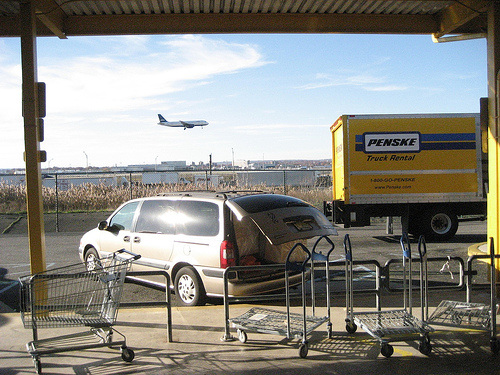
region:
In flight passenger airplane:
[156, 112, 210, 128]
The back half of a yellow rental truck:
[331, 113, 485, 236]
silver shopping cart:
[21, 253, 138, 369]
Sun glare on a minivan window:
[140, 200, 220, 236]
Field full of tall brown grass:
[46, 178, 126, 205]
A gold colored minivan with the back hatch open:
[90, 194, 327, 294]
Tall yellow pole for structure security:
[21, 27, 48, 312]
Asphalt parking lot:
[47, 237, 77, 268]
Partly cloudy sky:
[128, 38, 432, 99]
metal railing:
[138, 270, 179, 344]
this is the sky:
[232, 52, 297, 119]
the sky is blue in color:
[295, 40, 342, 67]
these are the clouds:
[158, 52, 207, 83]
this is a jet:
[151, 111, 210, 133]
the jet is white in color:
[193, 117, 208, 127]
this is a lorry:
[338, 106, 485, 235]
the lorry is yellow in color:
[421, 151, 474, 163]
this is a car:
[116, 190, 261, 251]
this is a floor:
[148, 338, 214, 369]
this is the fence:
[56, 175, 103, 205]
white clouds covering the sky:
[54, 75, 131, 127]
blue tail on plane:
[155, 112, 167, 132]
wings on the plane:
[173, 119, 205, 138]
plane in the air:
[133, 105, 246, 140]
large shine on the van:
[145, 193, 207, 234]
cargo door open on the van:
[215, 171, 353, 255]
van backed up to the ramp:
[78, 182, 328, 292]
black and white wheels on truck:
[415, 195, 460, 248]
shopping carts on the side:
[176, 233, 403, 348]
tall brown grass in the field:
[65, 179, 249, 196]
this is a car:
[135, 180, 226, 299]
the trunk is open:
[237, 198, 298, 261]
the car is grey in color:
[176, 239, 218, 267]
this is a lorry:
[335, 117, 452, 204]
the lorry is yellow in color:
[342, 120, 451, 190]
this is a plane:
[149, 109, 214, 135]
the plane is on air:
[155, 107, 215, 132]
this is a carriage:
[20, 248, 139, 362]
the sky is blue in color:
[319, 37, 406, 69]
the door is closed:
[110, 227, 131, 240]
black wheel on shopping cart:
[106, 335, 160, 365]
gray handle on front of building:
[133, 270, 203, 344]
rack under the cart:
[26, 331, 129, 351]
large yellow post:
[10, 85, 62, 285]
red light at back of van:
[209, 240, 246, 267]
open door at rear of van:
[188, 180, 352, 267]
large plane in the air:
[148, 113, 207, 133]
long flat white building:
[90, 152, 318, 193]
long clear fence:
[57, 165, 264, 205]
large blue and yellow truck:
[324, 115, 476, 205]